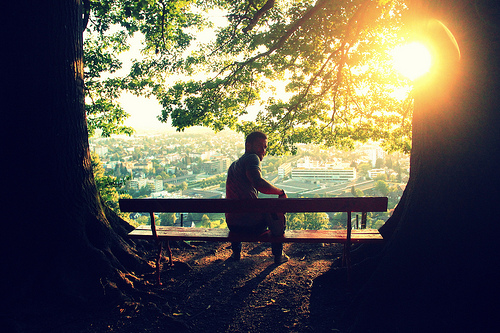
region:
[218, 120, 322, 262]
a person looking at the camera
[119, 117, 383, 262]
a person sitting on the bench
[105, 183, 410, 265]
a brown bench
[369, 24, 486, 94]
a sun in the sky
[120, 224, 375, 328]
a patch of brown dirt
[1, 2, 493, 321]
large trees on each side of the photo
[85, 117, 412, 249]
a city in the background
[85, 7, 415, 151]
some green branches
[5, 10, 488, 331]
a scene happening during the day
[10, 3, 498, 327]
a scene outside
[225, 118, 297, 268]
man sitting on wooden bench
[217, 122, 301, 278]
man wearing a grey tshirt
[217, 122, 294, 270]
man turning away from sunset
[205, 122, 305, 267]
man sitting between two large trees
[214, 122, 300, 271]
man wearing wristwatch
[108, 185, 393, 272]
long red wooden bench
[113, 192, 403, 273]
red bench placed between two trees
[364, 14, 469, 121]
bright orange sun in process of setting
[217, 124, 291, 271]
man with short hair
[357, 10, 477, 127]
setting sun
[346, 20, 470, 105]
sunlight coming through the trees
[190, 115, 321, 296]
a man sitting on a bench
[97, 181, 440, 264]
wooden bench between trees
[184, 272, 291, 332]
dirt and rocks on the ground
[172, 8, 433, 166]
branches of the trees hanging down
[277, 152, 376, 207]
a building on the ground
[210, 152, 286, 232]
a gray tee shirt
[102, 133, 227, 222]
houses and trees below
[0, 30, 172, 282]
a brown tree trunk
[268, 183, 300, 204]
a watch on a mans hand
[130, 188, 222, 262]
a bench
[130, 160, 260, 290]
a bench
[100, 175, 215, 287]
a bench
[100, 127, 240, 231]
a bench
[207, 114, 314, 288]
man is looking at camera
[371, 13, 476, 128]
sun shining behind tree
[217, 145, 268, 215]
man's shirt is gray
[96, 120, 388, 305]
man sitting on bench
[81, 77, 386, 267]
man sitting between tree trunks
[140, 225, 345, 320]
dirt is on ground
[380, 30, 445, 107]
the sun is orange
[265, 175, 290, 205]
something on man's wrist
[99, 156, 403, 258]
bench made of wood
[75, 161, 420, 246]
the bench is brown